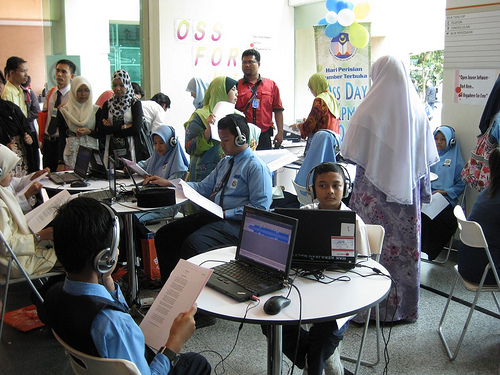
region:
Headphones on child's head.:
[302, 154, 371, 221]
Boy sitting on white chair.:
[343, 217, 392, 329]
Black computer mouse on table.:
[255, 277, 298, 329]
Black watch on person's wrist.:
[159, 340, 190, 369]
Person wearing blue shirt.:
[110, 314, 151, 373]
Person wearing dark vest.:
[38, 276, 115, 352]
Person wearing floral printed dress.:
[363, 186, 435, 322]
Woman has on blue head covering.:
[429, 130, 469, 207]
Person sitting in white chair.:
[437, 194, 494, 339]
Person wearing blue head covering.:
[297, 126, 356, 218]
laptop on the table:
[226, 212, 296, 283]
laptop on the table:
[293, 206, 370, 271]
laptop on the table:
[98, 160, 124, 202]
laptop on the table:
[56, 146, 99, 177]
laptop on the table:
[90, 152, 118, 182]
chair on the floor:
[442, 218, 497, 365]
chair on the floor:
[363, 223, 396, 374]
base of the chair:
[426, 314, 473, 360]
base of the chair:
[340, 352, 376, 362]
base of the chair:
[4, 283, 22, 342]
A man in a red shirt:
[225, 48, 286, 150]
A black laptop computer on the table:
[195, 198, 298, 301]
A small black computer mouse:
[261, 291, 290, 316]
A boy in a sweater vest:
[38, 195, 183, 370]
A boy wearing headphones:
[47, 194, 127, 284]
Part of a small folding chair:
[437, 204, 499, 366]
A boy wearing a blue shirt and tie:
[141, 114, 276, 280]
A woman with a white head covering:
[336, 54, 441, 203]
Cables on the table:
[292, 260, 384, 285]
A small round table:
[170, 228, 396, 373]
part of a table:
[322, 289, 326, 296]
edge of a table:
[283, 309, 290, 319]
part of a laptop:
[288, 250, 293, 269]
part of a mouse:
[278, 309, 283, 316]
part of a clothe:
[398, 255, 411, 305]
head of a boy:
[79, 231, 86, 243]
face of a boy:
[320, 165, 345, 202]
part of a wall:
[449, 97, 474, 140]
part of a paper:
[176, 290, 181, 307]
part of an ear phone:
[102, 264, 135, 270]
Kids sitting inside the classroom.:
[63, 137, 392, 361]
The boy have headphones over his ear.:
[40, 185, 128, 272]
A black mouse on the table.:
[259, 285, 302, 322]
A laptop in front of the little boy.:
[257, 187, 370, 272]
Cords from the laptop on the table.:
[292, 264, 357, 289]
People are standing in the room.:
[39, 58, 200, 178]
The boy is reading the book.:
[165, 111, 270, 225]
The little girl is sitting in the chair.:
[127, 116, 200, 179]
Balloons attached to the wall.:
[307, 4, 405, 67]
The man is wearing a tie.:
[31, 82, 79, 148]